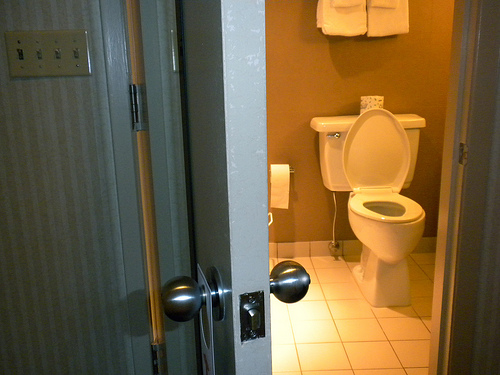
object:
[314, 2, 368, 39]
towel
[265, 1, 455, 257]
wall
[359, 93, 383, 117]
toilet paper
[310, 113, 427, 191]
tank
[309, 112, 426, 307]
toilet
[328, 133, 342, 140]
lever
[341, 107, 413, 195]
lid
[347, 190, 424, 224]
seat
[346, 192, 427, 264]
bowl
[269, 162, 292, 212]
toilet paper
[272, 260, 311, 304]
doorknob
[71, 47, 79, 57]
light switches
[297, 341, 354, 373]
tile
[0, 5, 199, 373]
wall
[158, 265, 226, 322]
handle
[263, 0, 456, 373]
restroom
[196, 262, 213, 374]
hanger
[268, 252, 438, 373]
floor